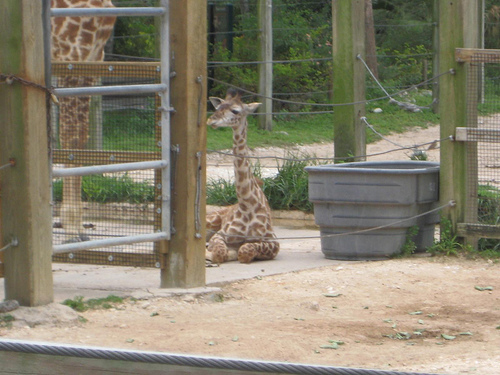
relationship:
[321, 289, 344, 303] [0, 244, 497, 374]
stone lying in dirt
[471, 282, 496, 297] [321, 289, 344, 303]
stone lying in stone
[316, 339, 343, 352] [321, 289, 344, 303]
stone lying in stone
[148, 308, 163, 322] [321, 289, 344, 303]
stone lying in stone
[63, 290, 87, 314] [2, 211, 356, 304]
weed growing from cement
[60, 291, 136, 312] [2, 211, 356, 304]
weed growing from cement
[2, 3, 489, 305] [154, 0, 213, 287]
fence bolted to post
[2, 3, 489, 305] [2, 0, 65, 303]
fence bolted to post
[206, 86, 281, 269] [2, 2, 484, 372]
giraffe lying in enclosure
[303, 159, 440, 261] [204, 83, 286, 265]
bin sitting beside giraffe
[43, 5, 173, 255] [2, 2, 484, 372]
gate surrounding enclosure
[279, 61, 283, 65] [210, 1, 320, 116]
leaf growing on tree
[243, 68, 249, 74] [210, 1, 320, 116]
leaf growing on tree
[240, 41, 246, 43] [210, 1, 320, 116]
leaf growing on tree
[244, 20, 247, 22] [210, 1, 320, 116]
leaf growing on tree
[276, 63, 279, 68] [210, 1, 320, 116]
leaf growing on tree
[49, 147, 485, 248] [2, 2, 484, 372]
grass growing in enclosure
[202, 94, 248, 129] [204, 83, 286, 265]
head belonging to giraffe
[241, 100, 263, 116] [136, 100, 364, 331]
ear belonging to giraffe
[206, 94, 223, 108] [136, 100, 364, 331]
ear belonging to giraffe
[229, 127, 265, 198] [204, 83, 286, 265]
neck belonging to giraffe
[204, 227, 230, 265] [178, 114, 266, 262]
leg belonging to giraffe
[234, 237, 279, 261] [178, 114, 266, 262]
leg belonging to giraffe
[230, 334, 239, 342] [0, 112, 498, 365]
leaf lying on ground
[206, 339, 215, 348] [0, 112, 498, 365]
leaf lying on ground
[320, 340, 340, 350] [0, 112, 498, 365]
leaf lying on ground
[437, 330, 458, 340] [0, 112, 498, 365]
leaf lying on ground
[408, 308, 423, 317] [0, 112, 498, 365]
leaf lying on ground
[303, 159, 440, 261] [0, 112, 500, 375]
bin by dirt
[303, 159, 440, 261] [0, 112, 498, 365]
bin on ground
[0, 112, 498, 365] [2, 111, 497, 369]
ground by dirt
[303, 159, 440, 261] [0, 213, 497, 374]
bin on ground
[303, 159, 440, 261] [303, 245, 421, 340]
bin beside dirt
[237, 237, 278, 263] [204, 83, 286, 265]
leg of giraffe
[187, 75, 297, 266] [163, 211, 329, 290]
giraffe sitting on ground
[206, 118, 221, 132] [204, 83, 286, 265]
mouth of giraffe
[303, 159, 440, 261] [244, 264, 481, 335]
bin on ground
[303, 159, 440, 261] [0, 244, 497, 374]
bin by dirt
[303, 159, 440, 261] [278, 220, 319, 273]
bin on ground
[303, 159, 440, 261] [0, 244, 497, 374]
bin on dirt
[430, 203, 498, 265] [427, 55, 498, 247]
weeds next to fence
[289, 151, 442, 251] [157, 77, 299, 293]
bin near giraffe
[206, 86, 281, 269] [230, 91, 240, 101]
giraffe has horn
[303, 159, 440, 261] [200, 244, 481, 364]
bin by dirt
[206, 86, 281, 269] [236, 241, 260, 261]
giraffe has knee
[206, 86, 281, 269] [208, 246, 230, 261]
giraffe has knee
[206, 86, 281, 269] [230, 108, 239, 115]
giraffe has eye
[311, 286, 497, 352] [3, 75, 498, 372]
greens on ground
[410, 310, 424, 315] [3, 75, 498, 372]
greens on ground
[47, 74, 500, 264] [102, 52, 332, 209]
grass on fence